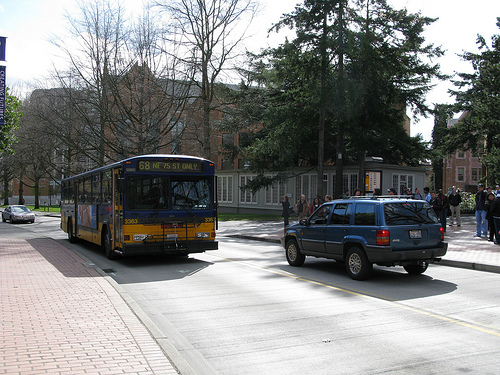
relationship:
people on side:
[421, 176, 500, 242] [451, 28, 487, 304]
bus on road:
[60, 140, 229, 262] [152, 270, 409, 343]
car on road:
[285, 201, 455, 282] [152, 270, 409, 343]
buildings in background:
[37, 85, 482, 186] [16, 14, 496, 146]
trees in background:
[214, 49, 497, 142] [16, 14, 496, 146]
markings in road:
[270, 289, 496, 338] [152, 270, 409, 343]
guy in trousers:
[448, 185, 470, 230] [450, 207, 463, 230]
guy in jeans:
[475, 179, 492, 244] [473, 213, 489, 241]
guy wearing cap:
[475, 179, 492, 244] [477, 179, 485, 190]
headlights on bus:
[131, 232, 214, 241] [60, 140, 229, 262]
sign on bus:
[71, 204, 104, 230] [60, 140, 229, 262]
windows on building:
[220, 177, 236, 205] [221, 167, 433, 202]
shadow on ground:
[218, 252, 293, 283] [201, 264, 355, 306]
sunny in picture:
[34, 3, 262, 43] [17, 11, 484, 321]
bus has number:
[60, 140, 229, 262] [136, 160, 151, 173]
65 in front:
[134, 155, 152, 174] [123, 149, 259, 254]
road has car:
[152, 270, 409, 343] [280, 196, 450, 280]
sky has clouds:
[16, 8, 266, 38] [20, 12, 49, 40]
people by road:
[421, 176, 500, 242] [152, 270, 409, 343]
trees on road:
[214, 49, 497, 142] [152, 270, 409, 343]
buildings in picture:
[37, 85, 482, 186] [17, 11, 484, 321]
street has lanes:
[206, 282, 500, 339] [260, 262, 458, 349]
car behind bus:
[5, 197, 41, 227] [60, 140, 229, 262]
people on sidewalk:
[421, 176, 500, 242] [448, 218, 499, 272]